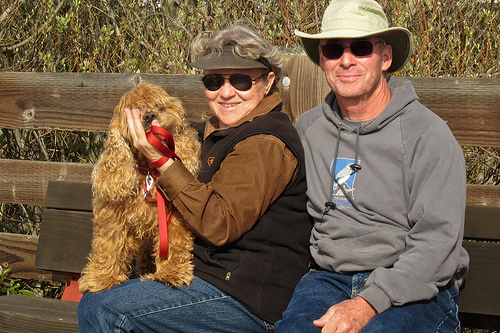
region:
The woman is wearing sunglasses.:
[187, 23, 287, 125]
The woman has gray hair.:
[186, 24, 288, 124]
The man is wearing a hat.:
[293, 1, 412, 98]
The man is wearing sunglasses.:
[294, 0, 416, 102]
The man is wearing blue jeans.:
[273, 252, 460, 330]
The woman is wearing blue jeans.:
[79, 269, 269, 331]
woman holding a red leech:
[129, 118, 181, 245]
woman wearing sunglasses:
[188, 68, 272, 95]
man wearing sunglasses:
[313, 40, 382, 70]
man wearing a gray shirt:
[300, 90, 461, 269]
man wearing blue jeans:
[304, 263, 436, 330]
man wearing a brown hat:
[294, 2, 406, 61]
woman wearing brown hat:
[181, 35, 263, 85]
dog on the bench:
[51, 63, 210, 297]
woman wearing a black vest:
[193, 122, 293, 307]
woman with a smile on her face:
[203, 92, 255, 116]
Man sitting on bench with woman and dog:
[275, 0, 466, 330]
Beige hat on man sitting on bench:
[292, 0, 412, 72]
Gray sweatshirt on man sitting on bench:
[292, 72, 468, 312]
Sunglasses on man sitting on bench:
[317, 38, 373, 58]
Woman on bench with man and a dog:
[75, 26, 305, 331]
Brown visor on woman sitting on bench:
[192, 47, 264, 69]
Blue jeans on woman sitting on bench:
[75, 270, 265, 331]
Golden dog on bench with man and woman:
[75, 82, 197, 292]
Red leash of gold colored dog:
[140, 123, 180, 255]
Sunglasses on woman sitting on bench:
[198, 70, 256, 91]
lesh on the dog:
[150, 212, 173, 255]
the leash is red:
[154, 230, 169, 258]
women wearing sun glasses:
[203, 75, 259, 90]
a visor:
[203, 51, 248, 70]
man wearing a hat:
[323, 8, 371, 33]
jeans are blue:
[126, 290, 163, 312]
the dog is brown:
[97, 163, 134, 223]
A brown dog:
[94, 86, 179, 256]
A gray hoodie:
[370, 139, 465, 252]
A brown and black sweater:
[222, 137, 299, 288]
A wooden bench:
[29, 182, 94, 261]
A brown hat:
[190, 44, 262, 72]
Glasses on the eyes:
[180, 73, 259, 95]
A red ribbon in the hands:
[152, 127, 179, 162]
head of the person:
[156, 12, 286, 137]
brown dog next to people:
[27, 101, 212, 279]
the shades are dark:
[200, 63, 257, 95]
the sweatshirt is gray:
[297, 106, 444, 281]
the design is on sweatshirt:
[320, 147, 372, 217]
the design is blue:
[330, 159, 366, 233]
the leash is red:
[147, 127, 177, 202]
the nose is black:
[142, 107, 159, 138]